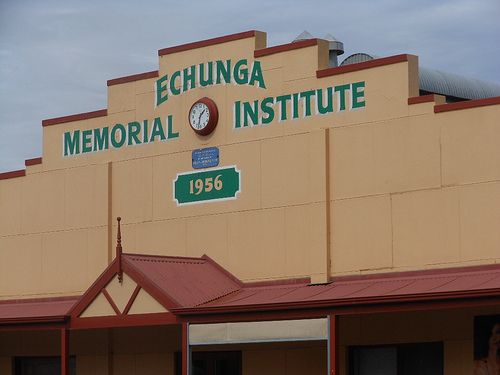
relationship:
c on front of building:
[169, 69, 182, 96] [48, 36, 465, 357]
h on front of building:
[181, 65, 197, 93] [4, 31, 498, 371]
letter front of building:
[59, 129, 83, 156] [4, 31, 498, 371]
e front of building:
[153, 75, 168, 106] [4, 31, 498, 371]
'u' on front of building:
[199, 54, 219, 94] [4, 31, 498, 371]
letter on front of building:
[229, 54, 248, 86] [4, 31, 498, 371]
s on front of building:
[255, 95, 276, 125] [48, 36, 465, 357]